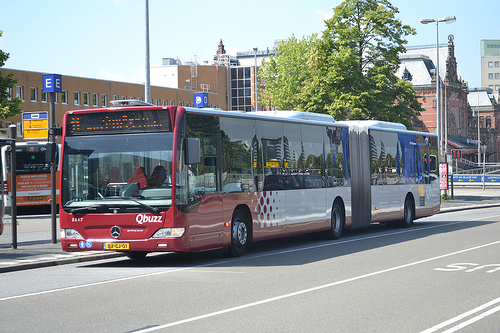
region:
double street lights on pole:
[420, 14, 460, 25]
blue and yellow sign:
[20, 108, 50, 140]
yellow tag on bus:
[102, 240, 132, 252]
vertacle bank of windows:
[229, 65, 254, 110]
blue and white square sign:
[43, 73, 63, 93]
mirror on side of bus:
[184, 135, 202, 166]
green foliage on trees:
[270, 56, 356, 112]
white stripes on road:
[214, 253, 421, 315]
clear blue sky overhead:
[32, 10, 108, 60]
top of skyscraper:
[212, 35, 227, 61]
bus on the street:
[56, 98, 468, 265]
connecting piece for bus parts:
[338, 117, 381, 229]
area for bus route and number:
[63, 110, 173, 137]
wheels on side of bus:
[220, 198, 423, 243]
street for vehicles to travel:
[41, 252, 491, 329]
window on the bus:
[222, 118, 342, 184]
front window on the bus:
[67, 138, 166, 200]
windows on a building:
[8, 80, 107, 107]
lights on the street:
[421, 12, 460, 29]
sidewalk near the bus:
[3, 247, 62, 257]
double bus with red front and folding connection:
[51, 100, 452, 257]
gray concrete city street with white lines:
[6, 209, 499, 330]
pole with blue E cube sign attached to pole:
[43, 73, 62, 237]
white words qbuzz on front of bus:
[136, 209, 163, 226]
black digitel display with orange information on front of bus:
[66, 110, 169, 142]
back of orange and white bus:
[1, 141, 68, 208]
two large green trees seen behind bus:
[253, 0, 438, 119]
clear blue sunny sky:
[7, 0, 499, 80]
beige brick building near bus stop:
[1, 50, 295, 128]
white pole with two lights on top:
[416, 9, 459, 199]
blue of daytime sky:
[1, 2, 498, 93]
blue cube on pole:
[38, 73, 63, 244]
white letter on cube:
[43, 73, 61, 93]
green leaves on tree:
[258, 1, 416, 118]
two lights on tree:
[416, 13, 456, 130]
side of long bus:
[58, 104, 438, 261]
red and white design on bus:
[186, 186, 350, 250]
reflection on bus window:
[214, 117, 346, 193]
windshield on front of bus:
[64, 132, 174, 202]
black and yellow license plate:
[103, 241, 132, 251]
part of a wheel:
[326, 220, 338, 238]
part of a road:
[386, 223, 396, 232]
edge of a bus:
[159, 163, 191, 208]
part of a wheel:
[329, 203, 336, 213]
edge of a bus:
[285, 182, 295, 195]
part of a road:
[386, 246, 390, 260]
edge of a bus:
[179, 218, 188, 226]